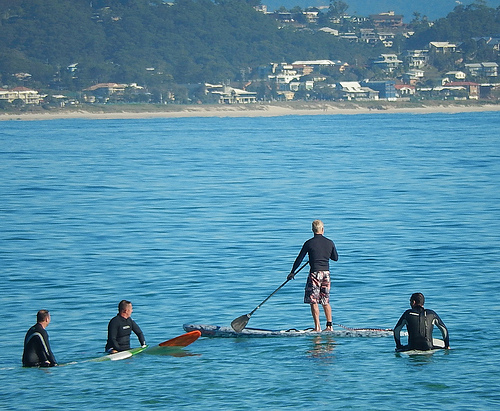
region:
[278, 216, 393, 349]
Man standing on surfboard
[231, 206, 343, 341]
Man standing holding paddle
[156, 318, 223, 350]
Orange tip on surfboard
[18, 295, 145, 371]
Two men in water wearing wetsuit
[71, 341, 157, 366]
Green and white surfboard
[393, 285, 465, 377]
Man halfway submerged in water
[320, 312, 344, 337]
ankle strap on man's leg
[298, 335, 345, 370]
Man's legs reflected in water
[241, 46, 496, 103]
Group of buildings near shore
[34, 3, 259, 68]
Bunch of trees in background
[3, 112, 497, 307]
The water is blue.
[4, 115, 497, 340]
The water is smooth.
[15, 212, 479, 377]
Four men in the water.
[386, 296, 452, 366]
The man's wet suit is black.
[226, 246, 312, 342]
An oar in the man's hand.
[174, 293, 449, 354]
The board is white.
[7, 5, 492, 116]
Buildings in the background.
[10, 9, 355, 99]
The leaves are green.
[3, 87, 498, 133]
The sand is tan.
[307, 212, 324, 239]
the man has blonde hair.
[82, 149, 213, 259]
light blue water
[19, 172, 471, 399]
four men in water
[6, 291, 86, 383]
bald man on surfboard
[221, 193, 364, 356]
man with a paddle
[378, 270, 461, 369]
man looking to left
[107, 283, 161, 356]
man in a wetsuit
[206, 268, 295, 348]
paddle in man's hand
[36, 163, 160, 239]
ripples in water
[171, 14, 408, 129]
houses on land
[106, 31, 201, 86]
trees on the land in background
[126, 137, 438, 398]
a man on a surf board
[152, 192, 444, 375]
a man paddling in the water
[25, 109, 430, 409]
four men in the water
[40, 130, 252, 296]
calm clear blue waters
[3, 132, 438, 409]
men in the calm water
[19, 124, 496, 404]
men in a body of water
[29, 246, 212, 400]
two men sitting on surfboard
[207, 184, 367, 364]
one man standing on surfboard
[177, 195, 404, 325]
one man holding paddle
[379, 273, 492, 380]
a man with a wetsuit on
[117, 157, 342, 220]
blue rippled ocean water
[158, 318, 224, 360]
orange nose of surfboard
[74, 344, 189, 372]
green and white surfboard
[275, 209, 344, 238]
man with blond hair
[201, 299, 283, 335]
black paddle with white stripe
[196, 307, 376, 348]
blue and white long board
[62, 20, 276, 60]
dark green forest area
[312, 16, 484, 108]
cascading building of the city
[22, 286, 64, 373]
man sitting on board missing crown of hair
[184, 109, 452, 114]
tan sand along the coastline